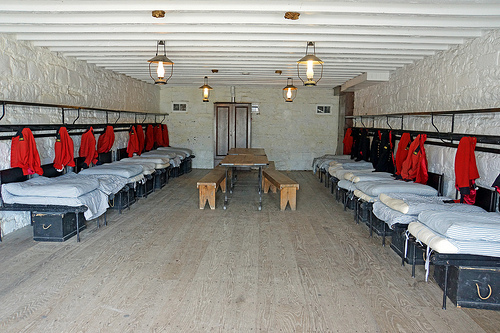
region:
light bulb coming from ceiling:
[140, 40, 182, 93]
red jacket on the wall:
[8, 124, 48, 176]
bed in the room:
[0, 167, 106, 209]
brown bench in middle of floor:
[259, 166, 308, 208]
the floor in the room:
[1, 244, 395, 331]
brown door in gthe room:
[212, 97, 254, 152]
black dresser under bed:
[27, 212, 79, 242]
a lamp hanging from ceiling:
[291, 35, 330, 93]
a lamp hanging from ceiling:
[276, 74, 299, 106]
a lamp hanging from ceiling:
[194, 73, 216, 105]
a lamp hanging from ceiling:
[148, 34, 175, 87]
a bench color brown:
[259, 157, 301, 211]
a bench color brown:
[194, 160, 229, 212]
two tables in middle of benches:
[199, 143, 296, 210]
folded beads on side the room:
[297, 145, 497, 300]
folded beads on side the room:
[36, 140, 180, 221]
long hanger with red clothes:
[1, 94, 176, 177]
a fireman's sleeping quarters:
[0, 1, 499, 328]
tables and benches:
[200, 146, 297, 211]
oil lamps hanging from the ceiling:
[148, 39, 323, 103]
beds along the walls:
[2, 145, 494, 281]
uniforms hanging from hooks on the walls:
[3, 121, 499, 203]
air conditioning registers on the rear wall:
[171, 101, 332, 113]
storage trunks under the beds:
[31, 154, 498, 305]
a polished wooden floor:
[1, 168, 496, 330]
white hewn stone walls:
[1, 28, 497, 241]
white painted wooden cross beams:
[1, 1, 498, 88]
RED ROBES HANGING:
[1, 120, 499, 201]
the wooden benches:
[198, 163, 298, 212]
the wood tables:
[222, 145, 270, 170]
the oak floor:
[0, 168, 494, 331]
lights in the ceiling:
[145, 35, 325, 105]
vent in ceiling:
[337, 72, 392, 93]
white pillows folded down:
[0, 146, 497, 256]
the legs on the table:
[223, 168, 262, 208]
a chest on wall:
[213, 98, 255, 158]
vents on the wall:
[173, 100, 331, 115]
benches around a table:
[185, 141, 316, 220]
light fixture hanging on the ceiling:
[141, 37, 181, 90]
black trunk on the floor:
[28, 206, 94, 243]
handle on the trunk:
[472, 280, 495, 302]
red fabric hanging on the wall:
[8, 128, 43, 175]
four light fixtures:
[140, 33, 342, 110]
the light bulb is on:
[305, 62, 317, 82]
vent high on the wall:
[311, 100, 335, 117]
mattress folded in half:
[1, 171, 100, 215]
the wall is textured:
[0, 38, 169, 262]